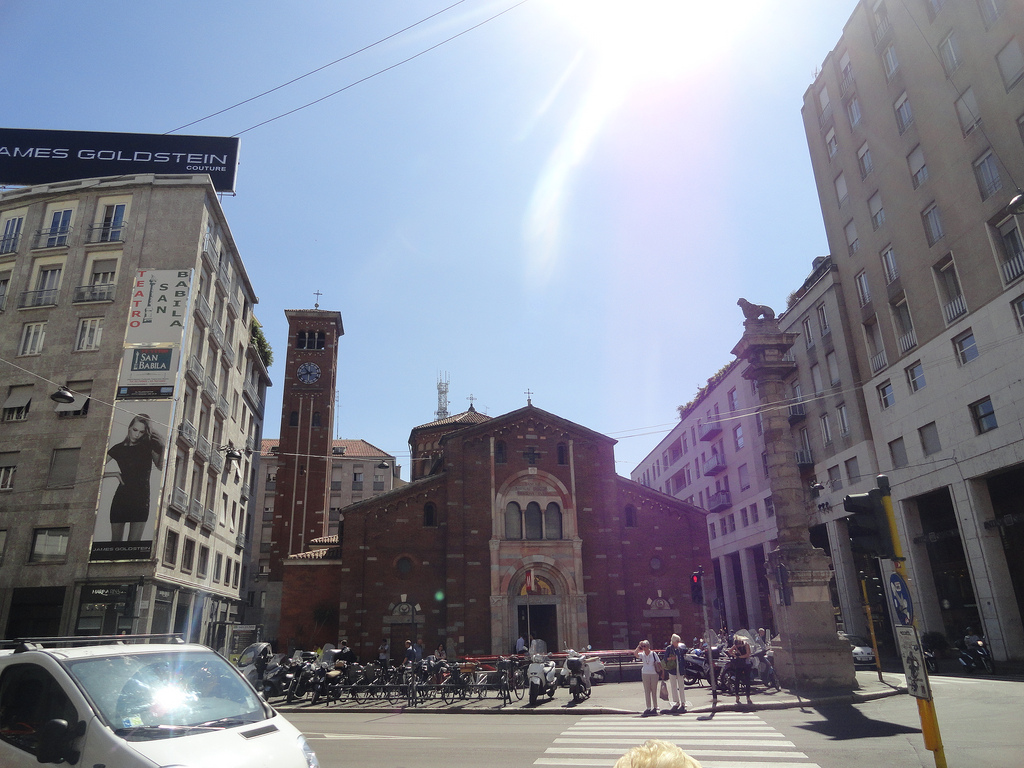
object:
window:
[878, 380, 896, 410]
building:
[799, 1, 1021, 666]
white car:
[2, 640, 311, 768]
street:
[279, 668, 1023, 766]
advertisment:
[88, 267, 197, 560]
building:
[0, 170, 262, 645]